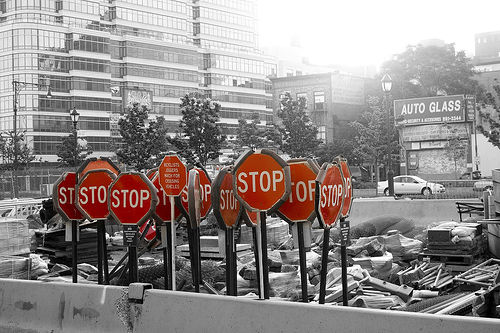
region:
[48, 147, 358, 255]
Bunch of stop signs in a supply yard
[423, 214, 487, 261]
Stack of sand bags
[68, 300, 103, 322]
Stain in the shape of a fish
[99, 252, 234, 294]
Rolled up fence laying on the ground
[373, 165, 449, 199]
Car parked in front of a business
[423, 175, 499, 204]
Portable metal gate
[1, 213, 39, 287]
Shrink wrapped pallet of supplies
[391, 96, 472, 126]
Store sign on top of a building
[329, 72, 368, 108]
Sign on the side of a building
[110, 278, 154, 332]
Damaged cement barracade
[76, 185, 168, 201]
A group of red and white stop signs.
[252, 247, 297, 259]
A group of red and white stop signs.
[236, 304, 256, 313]
A group of red and white stop signs.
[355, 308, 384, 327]
A group of red and white stop signs.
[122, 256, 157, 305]
A group of red and white stop signs.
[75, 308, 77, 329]
A group of red and white stop signs.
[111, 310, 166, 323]
A group of red and white stop signs.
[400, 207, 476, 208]
A group of red and white stop signs.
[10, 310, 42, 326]
A group of red and white stop signs.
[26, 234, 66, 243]
A group of red and white stop signs.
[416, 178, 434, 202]
a tire on a car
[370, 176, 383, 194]
a taillight on a car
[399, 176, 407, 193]
door handle on the side of the car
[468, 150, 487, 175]
a sign on a pole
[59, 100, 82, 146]
a light above the street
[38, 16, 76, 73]
windows in a building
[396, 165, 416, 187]
a window in the side of the car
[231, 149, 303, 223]
a sign with white letters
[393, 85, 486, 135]
a sign with a name of a business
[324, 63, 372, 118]
a sign on the side of the building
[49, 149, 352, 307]
Group of red stop signs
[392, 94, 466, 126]
Rectangular advertisement sign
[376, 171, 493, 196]
Two vehicles on a road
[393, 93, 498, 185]
Brick auto repair building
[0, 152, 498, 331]
Enclosed area of traffic supplies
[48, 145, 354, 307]
Group of new stop signs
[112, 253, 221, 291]
Rolls of metal netting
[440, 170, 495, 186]
Single door pickup truck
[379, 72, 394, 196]
Street lamp on a black pole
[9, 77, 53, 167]
Decorative metal street lamp